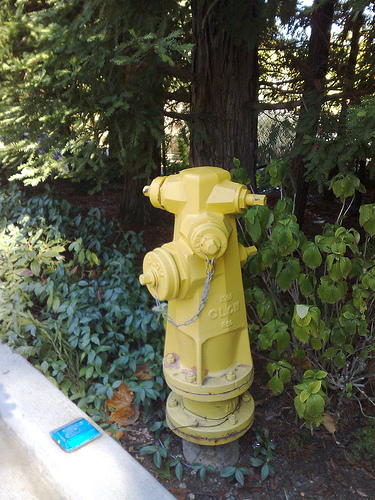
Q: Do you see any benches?
A: No, there are no benches.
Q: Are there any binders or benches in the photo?
A: No, there are no benches or binders.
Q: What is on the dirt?
A: The leaves are on the dirt.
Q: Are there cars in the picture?
A: No, there are no cars.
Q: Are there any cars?
A: No, there are no cars.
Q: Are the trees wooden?
A: Yes, the trees are wooden.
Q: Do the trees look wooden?
A: Yes, the trees are wooden.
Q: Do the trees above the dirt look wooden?
A: Yes, the trees are wooden.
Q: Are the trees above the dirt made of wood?
A: Yes, the trees are made of wood.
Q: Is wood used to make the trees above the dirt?
A: Yes, the trees are made of wood.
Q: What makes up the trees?
A: The trees are made of wood.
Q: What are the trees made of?
A: The trees are made of wood.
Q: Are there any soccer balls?
A: No, there are no soccer balls.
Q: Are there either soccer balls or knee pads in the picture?
A: No, there are no soccer balls or knee pads.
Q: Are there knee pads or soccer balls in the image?
A: No, there are no soccer balls or knee pads.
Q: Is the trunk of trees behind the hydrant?
A: Yes, the trunk is behind the hydrant.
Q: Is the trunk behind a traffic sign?
A: No, the trunk is behind the hydrant.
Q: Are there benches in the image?
A: No, there are no benches.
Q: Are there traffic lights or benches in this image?
A: No, there are no benches or traffic lights.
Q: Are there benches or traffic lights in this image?
A: No, there are no benches or traffic lights.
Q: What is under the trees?
A: The dirt is under the trees.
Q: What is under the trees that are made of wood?
A: The dirt is under the trees.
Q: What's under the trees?
A: The dirt is under the trees.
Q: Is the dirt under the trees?
A: Yes, the dirt is under the trees.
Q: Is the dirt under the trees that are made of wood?
A: Yes, the dirt is under the trees.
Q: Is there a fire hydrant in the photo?
A: Yes, there is a fire hydrant.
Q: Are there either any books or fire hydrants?
A: Yes, there is a fire hydrant.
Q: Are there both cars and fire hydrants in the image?
A: No, there is a fire hydrant but no cars.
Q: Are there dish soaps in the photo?
A: No, there are no dish soaps.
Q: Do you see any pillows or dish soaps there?
A: No, there are no dish soaps or pillows.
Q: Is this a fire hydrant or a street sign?
A: This is a fire hydrant.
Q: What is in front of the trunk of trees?
A: The fire hydrant is in front of the trunk.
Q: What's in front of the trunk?
A: The fire hydrant is in front of the trunk.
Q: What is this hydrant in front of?
A: The hydrant is in front of the trunk.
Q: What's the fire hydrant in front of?
A: The hydrant is in front of the trunk.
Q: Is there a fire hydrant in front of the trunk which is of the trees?
A: Yes, there is a fire hydrant in front of the trunk.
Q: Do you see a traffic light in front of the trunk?
A: No, there is a fire hydrant in front of the trunk.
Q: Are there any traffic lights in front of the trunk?
A: No, there is a fire hydrant in front of the trunk.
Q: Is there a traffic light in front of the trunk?
A: No, there is a fire hydrant in front of the trunk.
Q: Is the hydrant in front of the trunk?
A: Yes, the hydrant is in front of the trunk.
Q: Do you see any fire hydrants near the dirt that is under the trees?
A: Yes, there is a fire hydrant near the dirt.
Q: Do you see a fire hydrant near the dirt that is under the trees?
A: Yes, there is a fire hydrant near the dirt.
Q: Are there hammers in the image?
A: No, there are no hammers.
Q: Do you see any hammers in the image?
A: No, there are no hammers.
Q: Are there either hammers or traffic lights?
A: No, there are no hammers or traffic lights.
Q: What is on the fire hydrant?
A: The chain is on the fire hydrant.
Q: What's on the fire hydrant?
A: The chain is on the fire hydrant.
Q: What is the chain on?
A: The chain is on the hydrant.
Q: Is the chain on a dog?
A: No, the chain is on the hydrant.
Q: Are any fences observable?
A: Yes, there is a fence.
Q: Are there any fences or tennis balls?
A: Yes, there is a fence.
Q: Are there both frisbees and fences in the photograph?
A: No, there is a fence but no frisbees.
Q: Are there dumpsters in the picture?
A: No, there are no dumpsters.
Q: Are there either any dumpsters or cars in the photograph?
A: No, there are no dumpsters or cars.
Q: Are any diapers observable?
A: No, there are no diapers.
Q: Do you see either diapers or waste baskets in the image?
A: No, there are no diapers or waste baskets.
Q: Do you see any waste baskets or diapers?
A: No, there are no diapers or waste baskets.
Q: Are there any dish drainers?
A: No, there are no dish drainers.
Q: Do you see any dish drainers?
A: No, there are no dish drainers.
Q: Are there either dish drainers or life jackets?
A: No, there are no dish drainers or life jackets.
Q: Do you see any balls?
A: No, there are no balls.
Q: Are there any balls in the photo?
A: No, there are no balls.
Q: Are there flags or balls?
A: No, there are no balls or flags.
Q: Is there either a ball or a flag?
A: No, there are no balls or flags.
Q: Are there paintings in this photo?
A: No, there are no paintings.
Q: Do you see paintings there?
A: No, there are no paintings.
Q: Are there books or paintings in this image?
A: No, there are no paintings or books.